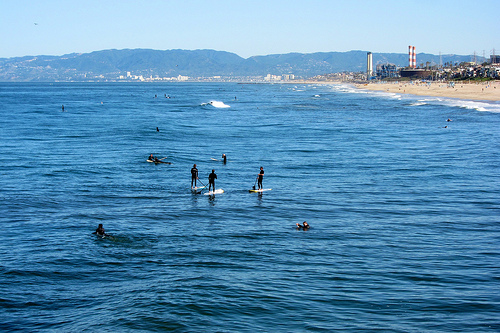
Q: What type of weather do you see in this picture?
A: It is clear.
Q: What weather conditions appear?
A: It is clear.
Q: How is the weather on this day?
A: It is clear.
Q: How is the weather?
A: It is clear.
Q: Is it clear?
A: Yes, it is clear.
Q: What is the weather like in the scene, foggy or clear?
A: It is clear.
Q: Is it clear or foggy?
A: It is clear.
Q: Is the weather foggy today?
A: No, it is clear.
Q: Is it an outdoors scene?
A: Yes, it is outdoors.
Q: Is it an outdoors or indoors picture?
A: It is outdoors.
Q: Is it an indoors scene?
A: No, it is outdoors.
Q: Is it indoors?
A: No, it is outdoors.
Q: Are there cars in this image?
A: No, there are no cars.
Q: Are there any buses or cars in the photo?
A: No, there are no cars or buses.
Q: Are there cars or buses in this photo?
A: No, there are no cars or buses.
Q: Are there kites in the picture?
A: No, there are no kites.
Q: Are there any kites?
A: No, there are no kites.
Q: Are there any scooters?
A: No, there are no scooters.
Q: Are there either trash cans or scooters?
A: No, there are no scooters or trash cans.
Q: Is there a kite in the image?
A: No, there are no kites.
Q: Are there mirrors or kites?
A: No, there are no kites or mirrors.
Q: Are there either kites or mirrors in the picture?
A: No, there are no kites or mirrors.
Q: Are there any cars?
A: No, there are no cars.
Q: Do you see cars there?
A: No, there are no cars.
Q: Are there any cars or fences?
A: No, there are no cars or fences.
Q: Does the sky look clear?
A: Yes, the sky is clear.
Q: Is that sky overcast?
A: No, the sky is clear.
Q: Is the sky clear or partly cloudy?
A: The sky is clear.